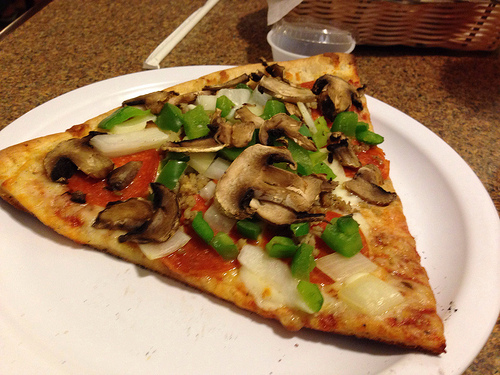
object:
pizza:
[0, 51, 447, 355]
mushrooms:
[213, 143, 313, 219]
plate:
[0, 65, 500, 374]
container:
[265, 25, 355, 63]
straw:
[141, 0, 218, 70]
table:
[0, 0, 221, 68]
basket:
[282, 0, 499, 55]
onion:
[333, 273, 406, 320]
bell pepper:
[321, 216, 364, 258]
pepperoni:
[41, 137, 116, 183]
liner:
[267, 0, 301, 27]